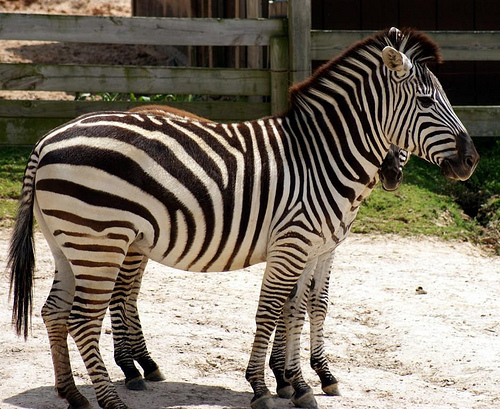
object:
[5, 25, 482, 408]
zebra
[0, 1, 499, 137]
fence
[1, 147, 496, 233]
grass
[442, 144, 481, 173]
nose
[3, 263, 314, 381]
shadow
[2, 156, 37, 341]
tail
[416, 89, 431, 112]
eye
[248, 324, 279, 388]
hoof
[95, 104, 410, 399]
friend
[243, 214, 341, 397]
leg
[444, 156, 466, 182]
mouth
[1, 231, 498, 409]
ground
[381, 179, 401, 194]
teeth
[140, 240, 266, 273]
belly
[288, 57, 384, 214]
neck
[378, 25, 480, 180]
head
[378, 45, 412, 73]
ear